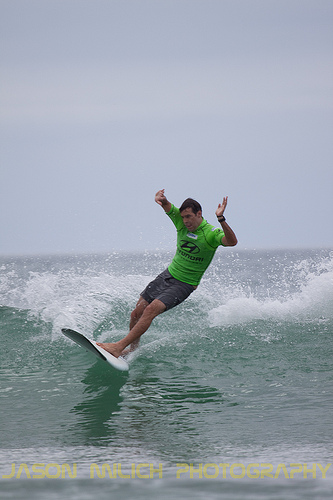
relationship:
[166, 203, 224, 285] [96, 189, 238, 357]
shirt on man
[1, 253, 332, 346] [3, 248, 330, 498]
wave in water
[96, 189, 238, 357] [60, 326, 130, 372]
man riding board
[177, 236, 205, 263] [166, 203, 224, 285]
logo on shirt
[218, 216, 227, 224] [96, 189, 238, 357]
watch on man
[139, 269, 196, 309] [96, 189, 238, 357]
shorts on man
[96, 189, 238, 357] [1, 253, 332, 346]
man riding wave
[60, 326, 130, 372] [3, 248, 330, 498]
board in water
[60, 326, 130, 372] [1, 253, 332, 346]
board on wave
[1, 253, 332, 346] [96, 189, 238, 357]
wave behind man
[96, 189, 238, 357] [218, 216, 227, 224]
man wearing watch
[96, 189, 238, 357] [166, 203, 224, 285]
man wearing shirt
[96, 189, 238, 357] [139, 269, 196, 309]
man wearing shorts